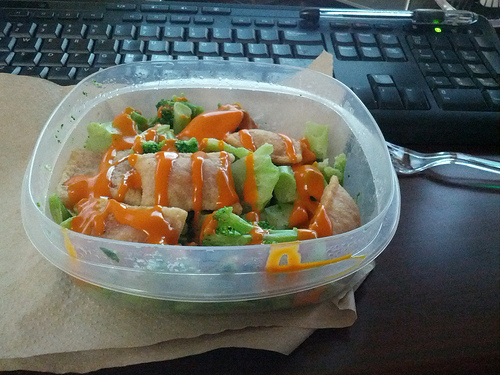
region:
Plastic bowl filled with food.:
[21, 56, 416, 312]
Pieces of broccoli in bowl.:
[196, 146, 304, 247]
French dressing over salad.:
[67, 164, 164, 238]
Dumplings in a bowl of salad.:
[133, 144, 244, 216]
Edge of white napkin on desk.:
[17, 284, 378, 372]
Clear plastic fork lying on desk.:
[391, 138, 497, 194]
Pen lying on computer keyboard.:
[297, 2, 489, 34]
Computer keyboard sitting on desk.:
[8, 16, 492, 121]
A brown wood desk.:
[421, 221, 487, 366]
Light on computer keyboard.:
[426, 21, 457, 44]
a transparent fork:
[448, 157, 464, 165]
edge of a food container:
[358, 212, 373, 242]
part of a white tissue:
[153, 334, 173, 349]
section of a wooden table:
[418, 286, 454, 339]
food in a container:
[204, 137, 277, 189]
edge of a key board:
[424, 110, 439, 127]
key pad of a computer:
[446, 87, 472, 95]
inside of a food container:
[230, 160, 373, 206]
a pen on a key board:
[388, 7, 458, 25]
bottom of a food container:
[318, 252, 344, 297]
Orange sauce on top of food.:
[114, 146, 239, 228]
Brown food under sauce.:
[121, 170, 149, 212]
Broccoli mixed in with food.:
[224, 164, 274, 289]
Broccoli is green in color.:
[216, 165, 251, 258]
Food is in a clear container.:
[140, 207, 319, 309]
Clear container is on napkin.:
[33, 187, 289, 366]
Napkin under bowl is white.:
[59, 290, 163, 369]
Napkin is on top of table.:
[253, 328, 365, 373]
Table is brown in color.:
[326, 316, 428, 370]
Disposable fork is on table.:
[420, 143, 455, 277]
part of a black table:
[410, 268, 452, 329]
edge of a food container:
[293, 235, 325, 262]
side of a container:
[301, 245, 349, 285]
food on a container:
[215, 134, 238, 181]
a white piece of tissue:
[46, 297, 96, 321]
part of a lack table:
[406, 266, 448, 327]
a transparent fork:
[414, 160, 434, 171]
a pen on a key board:
[325, 12, 453, 15]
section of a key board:
[437, 55, 458, 92]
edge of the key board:
[441, 111, 456, 129]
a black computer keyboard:
[1, 1, 499, 62]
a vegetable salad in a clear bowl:
[20, 58, 399, 306]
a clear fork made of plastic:
[386, 138, 498, 184]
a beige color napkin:
[1, 302, 391, 372]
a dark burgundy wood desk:
[402, 189, 499, 374]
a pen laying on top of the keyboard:
[298, 8, 477, 24]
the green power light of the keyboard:
[433, 24, 443, 34]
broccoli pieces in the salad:
[211, 206, 298, 242]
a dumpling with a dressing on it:
[226, 128, 302, 162]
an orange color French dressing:
[155, 152, 174, 203]